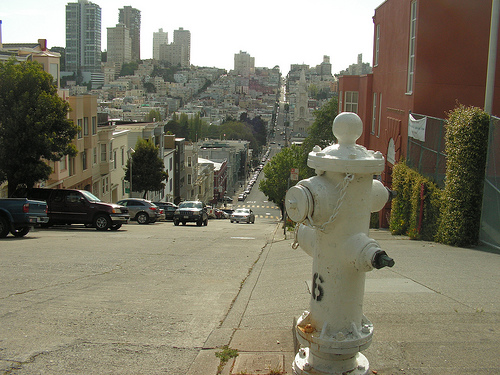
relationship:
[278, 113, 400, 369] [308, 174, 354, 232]
hydrant with chain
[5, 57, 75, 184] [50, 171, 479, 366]
tree on hill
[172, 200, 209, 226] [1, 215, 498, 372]
car traveling hill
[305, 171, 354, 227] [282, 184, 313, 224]
chain connected to cap